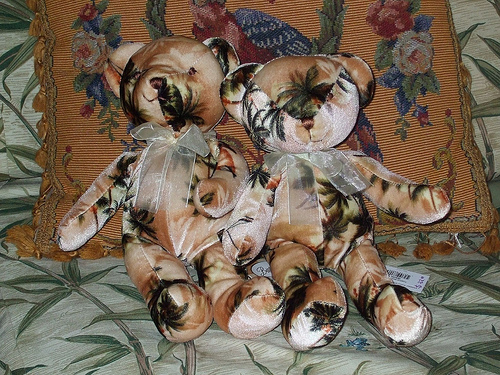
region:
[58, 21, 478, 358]
a pair of teddy bears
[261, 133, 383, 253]
a white gauzy bow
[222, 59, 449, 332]
a white tag on a toy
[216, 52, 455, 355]
a palm tree print bear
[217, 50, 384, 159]
teddy bear with brown nose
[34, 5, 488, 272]
a yellow embroidered pillow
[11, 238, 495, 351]
a green and tan comforter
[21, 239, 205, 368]
a bamboo print comforter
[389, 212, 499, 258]
a row of tassles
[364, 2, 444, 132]
a floral pattern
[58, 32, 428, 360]
There are two teddy bears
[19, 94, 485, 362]
The blanket is green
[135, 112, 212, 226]
The teddy bear has a white bow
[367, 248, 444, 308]
White and black tag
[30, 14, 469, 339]
Teddy bears are sitting up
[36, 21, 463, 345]
Teddy bears are leaning against a pillow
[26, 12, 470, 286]
Pillow is brown with flowers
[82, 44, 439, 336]
Teddy bears are brown with leaf patterns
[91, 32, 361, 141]
Teddy bears have brown eyes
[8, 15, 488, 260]
The pillow has brown tassles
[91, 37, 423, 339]
brown and black bears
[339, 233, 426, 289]
white tag on bear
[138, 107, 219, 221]
translucent bow on bear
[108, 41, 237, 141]
bear has black and brown face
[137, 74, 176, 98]
bear has brown nose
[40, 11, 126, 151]
bear on brown pillow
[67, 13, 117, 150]
pillow decorated with flowers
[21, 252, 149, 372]
green leaves on bedsheet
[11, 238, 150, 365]
brown vines on blanket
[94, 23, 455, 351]
bears with arms open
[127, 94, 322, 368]
stuffed toys are visible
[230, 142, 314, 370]
stuffed toys are visible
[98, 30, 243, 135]
the head of a teddy bear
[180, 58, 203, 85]
the eye of a teddy bear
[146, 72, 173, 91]
the nose of a teddy bear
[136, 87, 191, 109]
the mouth of a teddy bear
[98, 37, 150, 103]
the ear of a teddy bear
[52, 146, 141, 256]
the arm of a teddy bear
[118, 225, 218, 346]
the leg of a teddy bear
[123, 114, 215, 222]
a bow on the teddy bear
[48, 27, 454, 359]
two teddy bears on the bed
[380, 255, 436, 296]
a white tag